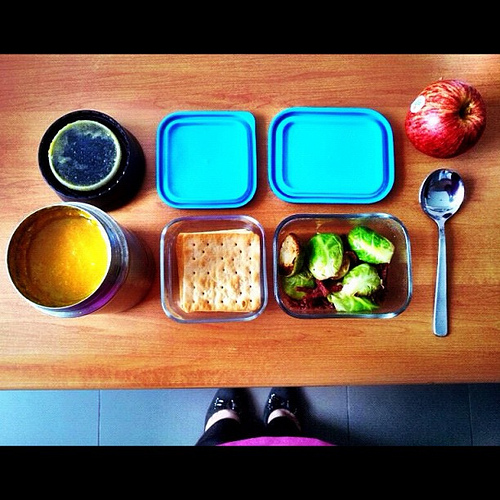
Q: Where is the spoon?
A: Next to the bowl.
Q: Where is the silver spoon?
A: On the table.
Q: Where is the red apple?
A: On the table.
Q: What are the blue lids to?
A: Glass containers.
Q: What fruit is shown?
A: Apple.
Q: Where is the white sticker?
A: On apple.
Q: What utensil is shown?
A: Spoon.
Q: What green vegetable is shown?
A: Brussel sprouts.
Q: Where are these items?
A: On table.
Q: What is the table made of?
A: Wood.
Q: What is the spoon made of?
A: Metal.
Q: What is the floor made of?
A: Tiles.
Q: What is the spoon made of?
A: Silver.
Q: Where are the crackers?
A: In a container.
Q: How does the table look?
A: Brown.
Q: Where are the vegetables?
A: In a bowl.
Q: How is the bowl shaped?
A: Rectangular.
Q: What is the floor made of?
A: Tiles.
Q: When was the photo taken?
A: Meal time.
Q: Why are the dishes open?
A: To expose food.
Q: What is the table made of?
A: Wood.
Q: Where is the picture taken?
A: A kitchen.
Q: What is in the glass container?
A: Salad.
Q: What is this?
A: Food.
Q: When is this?
A: Daytime.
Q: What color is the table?
A: Brown.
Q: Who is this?
A: Person.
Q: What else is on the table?
A: Spoon.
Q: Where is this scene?
A: At a table.